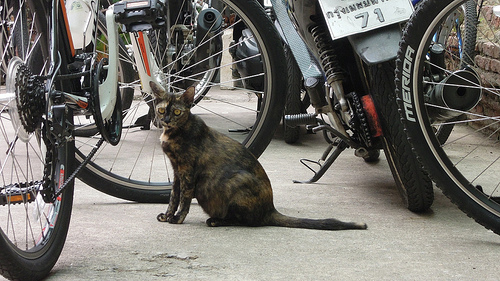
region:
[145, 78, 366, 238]
calico cat sitting with bikes outside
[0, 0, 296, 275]
bicycle with orange brake light on wheel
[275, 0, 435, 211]
motorcycle with number 71 on back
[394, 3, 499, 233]
front wheel of bicyclists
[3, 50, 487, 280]
concrete sidewalk area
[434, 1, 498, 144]
gray stone wall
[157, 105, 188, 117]
yellow alert eyes of cat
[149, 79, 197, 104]
pointy floppy ears of cat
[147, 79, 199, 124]
expression of cat looking grumpy and bewildered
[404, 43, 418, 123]
blue name of tire manufacturer on black tire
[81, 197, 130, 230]
this is the road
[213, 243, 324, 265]
the road is clean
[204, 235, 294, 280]
the road is grey in color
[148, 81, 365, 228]
this is a cat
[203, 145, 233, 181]
the fur is brown in color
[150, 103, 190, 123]
these are the eyes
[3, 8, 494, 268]
these are some bicycles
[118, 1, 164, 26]
this is a pedal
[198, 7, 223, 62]
this is an exhaust pipe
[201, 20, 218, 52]
the pipe is metallic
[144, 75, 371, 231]
a brown and black cat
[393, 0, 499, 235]
a spoked bicycle tire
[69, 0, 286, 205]
a spoked bicycle tire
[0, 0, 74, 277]
a spoked bicycle tire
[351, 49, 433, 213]
a motorcycle rear tire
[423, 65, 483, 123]
a motorcycle exhaust pipe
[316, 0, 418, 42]
a motorcycle white license plate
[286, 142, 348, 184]
a motorcycle kick stand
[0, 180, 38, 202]
a bicycle pedal with reflector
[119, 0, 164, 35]
a bicycle pedal with reflector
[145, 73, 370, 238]
brown calico cat sitting with bikes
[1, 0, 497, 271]
bicycle parked in street next to motorcycle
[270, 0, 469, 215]
motorcycle with blue paint and number 71 on plate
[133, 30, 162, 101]
orange brake light on bike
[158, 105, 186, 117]
piercing yellow eyes of cat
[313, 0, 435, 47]
license plate on back of moped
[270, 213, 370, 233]
long brown flat tail on cat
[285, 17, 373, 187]
blue motorcycle with with steel accents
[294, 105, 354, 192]
bike prop for motorcycle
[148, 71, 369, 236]
brown, black, and gold tabby cat sitting on hind quarters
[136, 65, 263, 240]
the cat is sitted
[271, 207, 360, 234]
this is the tail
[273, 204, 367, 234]
the tail is long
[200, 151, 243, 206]
the cat is brown in color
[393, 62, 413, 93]
this is the wheel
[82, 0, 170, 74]
this is the pedal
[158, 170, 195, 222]
these are the front legs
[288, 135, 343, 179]
this is the stand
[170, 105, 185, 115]
the eye is open